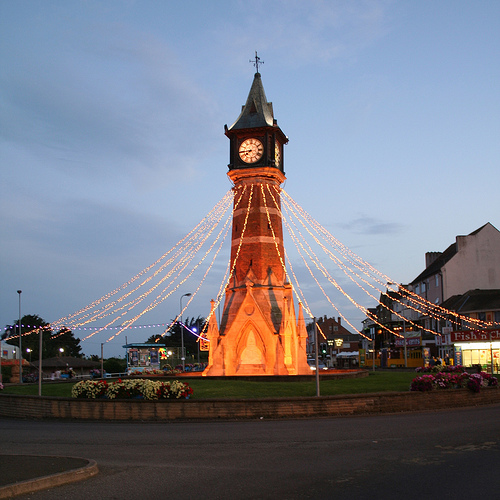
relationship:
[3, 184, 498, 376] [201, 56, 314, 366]
lights on pole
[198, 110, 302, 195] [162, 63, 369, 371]
clock on tower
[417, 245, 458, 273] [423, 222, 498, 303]
roof on building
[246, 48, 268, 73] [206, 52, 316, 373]
weathervane on tower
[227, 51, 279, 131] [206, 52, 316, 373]
steeple on tower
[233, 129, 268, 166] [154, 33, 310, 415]
clock in front of tower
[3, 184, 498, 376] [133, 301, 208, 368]
lights on pole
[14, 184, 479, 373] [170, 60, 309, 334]
lights leading to tower